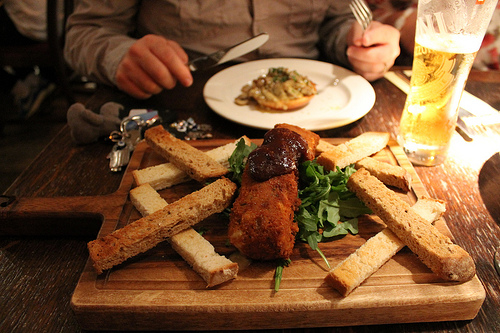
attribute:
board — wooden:
[118, 123, 470, 302]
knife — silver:
[180, 31, 259, 73]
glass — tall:
[398, 2, 484, 147]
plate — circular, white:
[201, 54, 379, 127]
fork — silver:
[348, 5, 379, 34]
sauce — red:
[236, 135, 307, 179]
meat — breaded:
[240, 124, 298, 245]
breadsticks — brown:
[98, 122, 258, 300]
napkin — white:
[399, 66, 482, 136]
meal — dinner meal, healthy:
[54, 140, 446, 303]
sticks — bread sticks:
[93, 131, 233, 291]